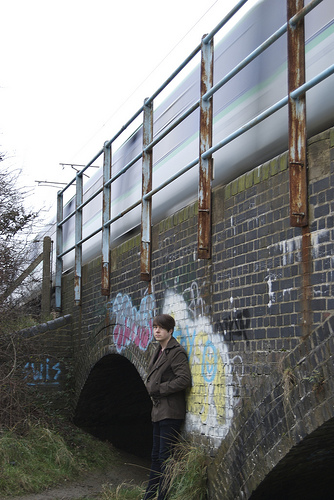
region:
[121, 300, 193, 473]
A man leaning on the wall.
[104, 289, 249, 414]
grafitti on the wall.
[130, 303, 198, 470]
A man standing under the bridge.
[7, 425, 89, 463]
weeds on the ground.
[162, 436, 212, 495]
Weeds growing on the wall of bridge.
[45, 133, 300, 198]
Train on the tracks of the bridge.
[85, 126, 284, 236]
Railing on the bridge.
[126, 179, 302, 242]
The railing is rusty.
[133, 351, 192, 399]
Person has hands in pocket.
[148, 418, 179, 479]
Person wearing long dark pants.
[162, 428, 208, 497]
Grass growing on side of bridge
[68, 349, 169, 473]
Tunnel going under the bridge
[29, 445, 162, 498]
Dirt path going under bridge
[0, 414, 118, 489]
Green grass growing on the ground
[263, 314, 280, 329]
Bridge made out of cinderblocks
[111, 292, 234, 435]
Graffitti on side of bridge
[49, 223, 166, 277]
Guard rails on side of bridge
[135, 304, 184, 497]
Young man with long hair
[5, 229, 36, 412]
Part of dead tree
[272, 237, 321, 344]
Rust marks on side of the bridge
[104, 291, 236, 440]
Graffiti on side of cinder block bridge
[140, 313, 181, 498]
Young boy leaning on the bridge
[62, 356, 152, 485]
Passage way under the bridge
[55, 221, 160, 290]
Guard rails along top of bridge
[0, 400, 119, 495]
Green grass on the ground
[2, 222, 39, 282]
The sky is clear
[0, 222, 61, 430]
Tree without any leaves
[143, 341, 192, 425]
Long sleeve brown coat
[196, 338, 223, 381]
Blue smiley face graffiti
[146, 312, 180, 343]
Long comb over on young man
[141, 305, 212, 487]
a lady standing beside a bridge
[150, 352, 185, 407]
the jacket is grey in color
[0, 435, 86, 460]
the grass is green in color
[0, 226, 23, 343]
the trees are brown in color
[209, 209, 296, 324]
the wall is black bricked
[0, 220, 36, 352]
the plants are dried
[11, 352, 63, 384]
words are written in light blue color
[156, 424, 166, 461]
trouser is black in color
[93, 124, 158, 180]
the pipes are metalic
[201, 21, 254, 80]
metals are light blue in color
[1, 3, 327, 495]
an old bridge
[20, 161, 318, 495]
man leans on wall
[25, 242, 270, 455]
graffiti on a wall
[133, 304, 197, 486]
man has hands on pocket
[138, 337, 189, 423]
a brown coat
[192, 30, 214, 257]
the pole is rust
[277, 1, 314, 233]
the pole is rust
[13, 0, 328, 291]
the rail of bridge is rusty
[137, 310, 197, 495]
man wears a brown coat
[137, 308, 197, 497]
man wears black pants